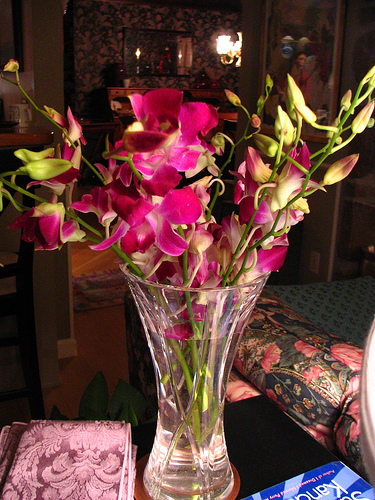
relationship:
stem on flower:
[178, 226, 201, 377] [90, 186, 203, 256]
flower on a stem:
[22, 200, 72, 255] [2, 169, 183, 344]